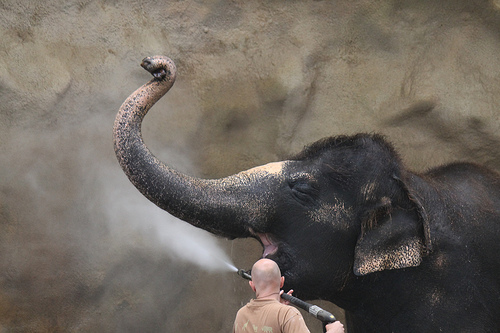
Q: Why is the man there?
A: Cleaning elephant.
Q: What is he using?
A: Water hose.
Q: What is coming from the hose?
A: Water.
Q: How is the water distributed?
A: Spraying.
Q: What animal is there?
A: Elephant.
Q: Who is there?
A: Man.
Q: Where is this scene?
A: In the zoo.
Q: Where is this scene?
A: Close to an elephant.